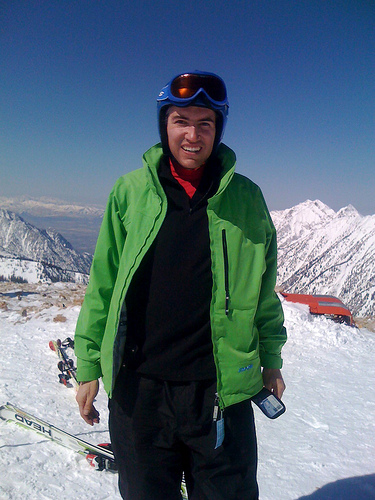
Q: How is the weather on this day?
A: It is clear.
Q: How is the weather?
A: It is clear.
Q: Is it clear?
A: Yes, it is clear.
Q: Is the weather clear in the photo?
A: Yes, it is clear.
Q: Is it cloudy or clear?
A: It is clear.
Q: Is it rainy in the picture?
A: No, it is clear.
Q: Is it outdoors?
A: Yes, it is outdoors.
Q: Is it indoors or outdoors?
A: It is outdoors.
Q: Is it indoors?
A: No, it is outdoors.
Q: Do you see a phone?
A: Yes, there is a phone.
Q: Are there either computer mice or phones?
A: Yes, there is a phone.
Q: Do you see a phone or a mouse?
A: Yes, there is a phone.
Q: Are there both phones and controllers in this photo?
A: No, there is a phone but no controllers.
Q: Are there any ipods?
A: No, there are no ipods.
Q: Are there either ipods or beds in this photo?
A: No, there are no ipods or beds.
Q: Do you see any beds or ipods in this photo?
A: No, there are no ipods or beds.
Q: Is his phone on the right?
A: Yes, the telephone is on the right of the image.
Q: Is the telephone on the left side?
A: No, the telephone is on the right of the image.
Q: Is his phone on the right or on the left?
A: The telephone is on the right of the image.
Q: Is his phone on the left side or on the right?
A: The telephone is on the right of the image.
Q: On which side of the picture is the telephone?
A: The telephone is on the right of the image.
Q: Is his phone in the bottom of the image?
A: Yes, the telephone is in the bottom of the image.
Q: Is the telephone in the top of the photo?
A: No, the telephone is in the bottom of the image.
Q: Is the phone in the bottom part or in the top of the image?
A: The phone is in the bottom of the image.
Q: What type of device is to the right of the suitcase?
A: The device is a phone.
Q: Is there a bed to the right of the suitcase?
A: No, there is a phone to the right of the suitcase.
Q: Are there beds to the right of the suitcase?
A: No, there is a phone to the right of the suitcase.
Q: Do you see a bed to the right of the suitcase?
A: No, there is a phone to the right of the suitcase.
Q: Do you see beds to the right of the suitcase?
A: No, there is a phone to the right of the suitcase.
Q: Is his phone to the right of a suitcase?
A: Yes, the phone is to the right of a suitcase.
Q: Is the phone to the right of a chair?
A: No, the phone is to the right of a suitcase.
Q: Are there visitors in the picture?
A: No, there are no visitors.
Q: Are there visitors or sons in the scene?
A: No, there are no visitors or sons.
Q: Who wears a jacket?
A: The man wears a jacket.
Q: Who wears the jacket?
A: The man wears a jacket.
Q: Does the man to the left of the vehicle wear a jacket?
A: Yes, the man wears a jacket.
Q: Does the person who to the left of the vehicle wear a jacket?
A: Yes, the man wears a jacket.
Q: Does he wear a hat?
A: No, the man wears a jacket.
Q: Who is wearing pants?
A: The man is wearing pants.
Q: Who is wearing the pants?
A: The man is wearing pants.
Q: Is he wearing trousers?
A: Yes, the man is wearing trousers.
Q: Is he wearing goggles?
A: No, the man is wearing trousers.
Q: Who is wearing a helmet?
A: The man is wearing a helmet.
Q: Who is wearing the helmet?
A: The man is wearing a helmet.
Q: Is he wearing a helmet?
A: Yes, the man is wearing a helmet.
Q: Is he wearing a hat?
A: No, the man is wearing a helmet.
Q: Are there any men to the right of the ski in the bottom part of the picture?
A: Yes, there is a man to the right of the ski.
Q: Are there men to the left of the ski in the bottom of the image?
A: No, the man is to the right of the ski.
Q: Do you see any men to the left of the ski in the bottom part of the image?
A: No, the man is to the right of the ski.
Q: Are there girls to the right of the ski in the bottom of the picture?
A: No, there is a man to the right of the ski.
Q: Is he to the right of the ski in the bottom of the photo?
A: Yes, the man is to the right of the ski.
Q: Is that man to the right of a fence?
A: No, the man is to the right of the ski.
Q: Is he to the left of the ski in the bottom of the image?
A: No, the man is to the right of the ski.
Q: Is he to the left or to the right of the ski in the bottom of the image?
A: The man is to the right of the ski.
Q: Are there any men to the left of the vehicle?
A: Yes, there is a man to the left of the vehicle.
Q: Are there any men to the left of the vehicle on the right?
A: Yes, there is a man to the left of the vehicle.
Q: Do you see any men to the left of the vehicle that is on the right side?
A: Yes, there is a man to the left of the vehicle.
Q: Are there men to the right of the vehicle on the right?
A: No, the man is to the left of the vehicle.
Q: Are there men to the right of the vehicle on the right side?
A: No, the man is to the left of the vehicle.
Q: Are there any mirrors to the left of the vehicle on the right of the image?
A: No, there is a man to the left of the vehicle.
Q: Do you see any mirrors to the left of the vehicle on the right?
A: No, there is a man to the left of the vehicle.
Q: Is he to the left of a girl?
A: No, the man is to the left of the vehicle.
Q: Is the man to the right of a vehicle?
A: No, the man is to the left of a vehicle.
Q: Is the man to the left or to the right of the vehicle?
A: The man is to the left of the vehicle.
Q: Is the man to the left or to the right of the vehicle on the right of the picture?
A: The man is to the left of the vehicle.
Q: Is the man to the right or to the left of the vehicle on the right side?
A: The man is to the left of the vehicle.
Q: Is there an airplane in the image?
A: No, there are no airplanes.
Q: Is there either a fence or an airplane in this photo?
A: No, there are no airplanes or fences.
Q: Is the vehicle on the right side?
A: Yes, the vehicle is on the right of the image.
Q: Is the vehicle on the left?
A: No, the vehicle is on the right of the image.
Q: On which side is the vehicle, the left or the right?
A: The vehicle is on the right of the image.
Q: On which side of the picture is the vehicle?
A: The vehicle is on the right of the image.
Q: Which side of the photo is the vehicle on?
A: The vehicle is on the right of the image.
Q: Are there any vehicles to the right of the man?
A: Yes, there is a vehicle to the right of the man.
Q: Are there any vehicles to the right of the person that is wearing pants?
A: Yes, there is a vehicle to the right of the man.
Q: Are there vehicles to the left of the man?
A: No, the vehicle is to the right of the man.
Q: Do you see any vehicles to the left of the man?
A: No, the vehicle is to the right of the man.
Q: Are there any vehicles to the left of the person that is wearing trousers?
A: No, the vehicle is to the right of the man.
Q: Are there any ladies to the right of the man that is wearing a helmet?
A: No, there is a vehicle to the right of the man.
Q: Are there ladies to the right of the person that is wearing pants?
A: No, there is a vehicle to the right of the man.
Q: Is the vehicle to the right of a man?
A: Yes, the vehicle is to the right of a man.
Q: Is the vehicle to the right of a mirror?
A: No, the vehicle is to the right of a man.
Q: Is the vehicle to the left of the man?
A: No, the vehicle is to the right of the man.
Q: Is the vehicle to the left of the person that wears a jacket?
A: No, the vehicle is to the right of the man.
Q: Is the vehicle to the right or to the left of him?
A: The vehicle is to the right of the man.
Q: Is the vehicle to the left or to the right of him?
A: The vehicle is to the right of the man.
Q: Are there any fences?
A: No, there are no fences.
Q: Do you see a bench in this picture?
A: No, there are no benches.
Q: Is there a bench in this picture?
A: No, there are no benches.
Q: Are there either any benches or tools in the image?
A: No, there are no benches or tools.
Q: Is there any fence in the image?
A: No, there are no fences.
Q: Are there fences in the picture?
A: No, there are no fences.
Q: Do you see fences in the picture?
A: No, there are no fences.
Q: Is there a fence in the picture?
A: No, there are no fences.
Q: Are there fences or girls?
A: No, there are no fences or girls.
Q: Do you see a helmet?
A: Yes, there is a helmet.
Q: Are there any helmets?
A: Yes, there is a helmet.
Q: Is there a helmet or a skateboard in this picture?
A: Yes, there is a helmet.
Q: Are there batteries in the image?
A: No, there are no batteries.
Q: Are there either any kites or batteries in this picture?
A: No, there are no batteries or kites.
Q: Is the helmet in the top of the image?
A: Yes, the helmet is in the top of the image.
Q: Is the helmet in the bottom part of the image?
A: No, the helmet is in the top of the image.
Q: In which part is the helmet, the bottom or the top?
A: The helmet is in the top of the image.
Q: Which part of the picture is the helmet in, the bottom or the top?
A: The helmet is in the top of the image.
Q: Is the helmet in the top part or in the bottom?
A: The helmet is in the top of the image.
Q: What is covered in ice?
A: The mountain is covered in ice.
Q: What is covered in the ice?
A: The mountain is covered in ice.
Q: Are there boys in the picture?
A: No, there are no boys.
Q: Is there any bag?
A: No, there are no bags.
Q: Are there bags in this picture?
A: No, there are no bags.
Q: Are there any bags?
A: No, there are no bags.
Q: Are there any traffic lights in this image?
A: No, there are no traffic lights.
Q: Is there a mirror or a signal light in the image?
A: No, there are no traffic lights or mirrors.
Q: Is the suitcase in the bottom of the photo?
A: Yes, the suitcase is in the bottom of the image.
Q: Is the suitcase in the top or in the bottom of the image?
A: The suitcase is in the bottom of the image.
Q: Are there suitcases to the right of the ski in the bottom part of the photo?
A: Yes, there is a suitcase to the right of the ski.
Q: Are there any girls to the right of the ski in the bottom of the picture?
A: No, there is a suitcase to the right of the ski.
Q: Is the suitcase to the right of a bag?
A: No, the suitcase is to the right of the ski.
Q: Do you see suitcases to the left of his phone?
A: Yes, there is a suitcase to the left of the phone.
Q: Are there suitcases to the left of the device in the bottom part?
A: Yes, there is a suitcase to the left of the phone.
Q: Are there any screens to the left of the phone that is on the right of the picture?
A: No, there is a suitcase to the left of the telephone.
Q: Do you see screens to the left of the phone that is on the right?
A: No, there is a suitcase to the left of the telephone.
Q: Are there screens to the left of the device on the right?
A: No, there is a suitcase to the left of the telephone.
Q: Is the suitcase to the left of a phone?
A: Yes, the suitcase is to the left of a phone.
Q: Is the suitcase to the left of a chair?
A: No, the suitcase is to the left of a phone.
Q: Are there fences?
A: No, there are no fences.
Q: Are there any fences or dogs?
A: No, there are no fences or dogs.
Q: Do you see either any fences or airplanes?
A: No, there are no fences or airplanes.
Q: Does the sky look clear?
A: Yes, the sky is clear.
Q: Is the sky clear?
A: Yes, the sky is clear.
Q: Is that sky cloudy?
A: No, the sky is clear.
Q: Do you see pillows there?
A: No, there are no pillows.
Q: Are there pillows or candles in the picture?
A: No, there are no pillows or candles.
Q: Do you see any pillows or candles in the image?
A: No, there are no pillows or candles.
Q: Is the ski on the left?
A: Yes, the ski is on the left of the image.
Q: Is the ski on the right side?
A: No, the ski is on the left of the image.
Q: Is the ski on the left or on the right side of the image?
A: The ski is on the left of the image.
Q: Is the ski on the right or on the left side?
A: The ski is on the left of the image.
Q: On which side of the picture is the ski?
A: The ski is on the left of the image.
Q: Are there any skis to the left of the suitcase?
A: Yes, there is a ski to the left of the suitcase.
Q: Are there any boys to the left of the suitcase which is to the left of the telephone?
A: No, there is a ski to the left of the suitcase.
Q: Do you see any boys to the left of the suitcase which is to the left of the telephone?
A: No, there is a ski to the left of the suitcase.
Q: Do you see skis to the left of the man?
A: Yes, there is a ski to the left of the man.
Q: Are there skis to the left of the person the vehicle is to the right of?
A: Yes, there is a ski to the left of the man.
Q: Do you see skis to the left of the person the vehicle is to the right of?
A: Yes, there is a ski to the left of the man.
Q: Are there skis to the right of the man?
A: No, the ski is to the left of the man.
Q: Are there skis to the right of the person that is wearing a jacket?
A: No, the ski is to the left of the man.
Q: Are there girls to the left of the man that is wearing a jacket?
A: No, there is a ski to the left of the man.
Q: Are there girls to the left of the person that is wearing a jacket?
A: No, there is a ski to the left of the man.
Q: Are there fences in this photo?
A: No, there are no fences.